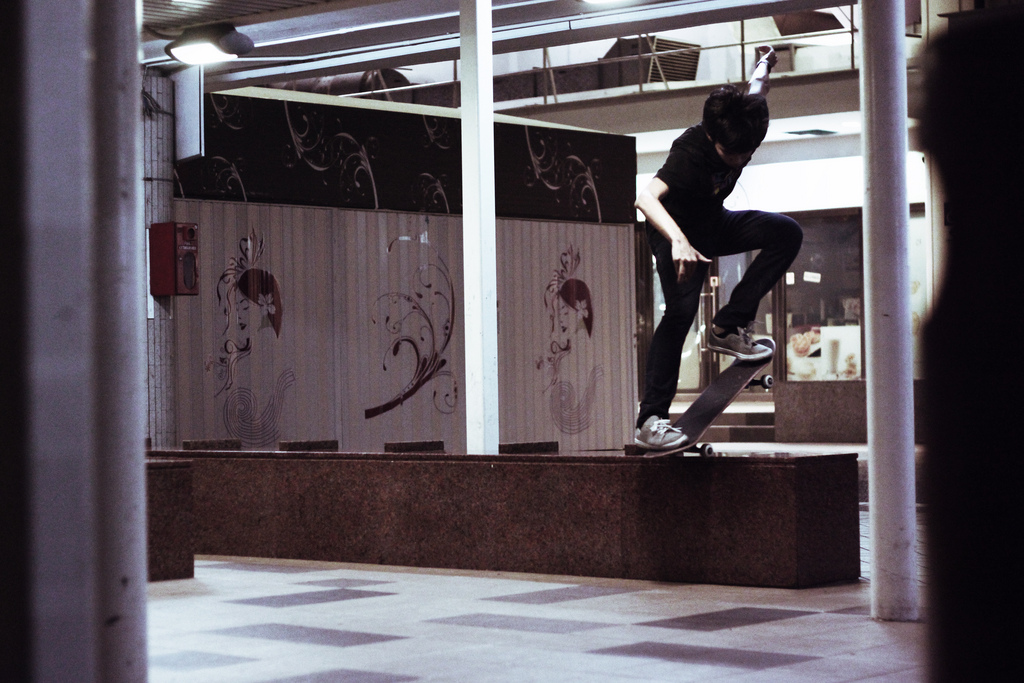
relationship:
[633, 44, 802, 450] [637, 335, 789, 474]
guy on a skateboard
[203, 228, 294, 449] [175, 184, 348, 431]
design on wall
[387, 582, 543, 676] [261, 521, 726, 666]
tile on floor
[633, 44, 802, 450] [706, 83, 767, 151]
guy with hair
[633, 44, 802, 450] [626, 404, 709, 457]
guy wearing shoe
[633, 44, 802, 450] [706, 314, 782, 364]
guy wearing shoe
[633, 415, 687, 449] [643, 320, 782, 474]
shoe on skateboard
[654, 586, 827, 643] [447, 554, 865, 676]
tile on floor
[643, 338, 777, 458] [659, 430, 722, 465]
skateboard with wheel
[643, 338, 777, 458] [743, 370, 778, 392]
skateboard with wheel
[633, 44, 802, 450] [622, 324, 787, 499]
guy on a skateboard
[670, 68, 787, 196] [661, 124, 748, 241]
guy wearing a shirt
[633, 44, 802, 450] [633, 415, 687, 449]
guy wearing shoe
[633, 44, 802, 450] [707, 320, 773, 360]
guy wearing shoe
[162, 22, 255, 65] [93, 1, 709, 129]
light on ceiling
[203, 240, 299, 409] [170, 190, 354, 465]
design on wall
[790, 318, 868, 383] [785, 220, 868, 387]
posters on window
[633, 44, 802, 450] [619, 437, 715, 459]
guy on skateboard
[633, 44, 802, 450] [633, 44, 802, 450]
guy doing guy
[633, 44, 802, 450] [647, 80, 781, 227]
guy wears shirt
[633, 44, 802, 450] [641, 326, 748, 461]
guy wears shoes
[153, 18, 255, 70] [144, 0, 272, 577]
light on side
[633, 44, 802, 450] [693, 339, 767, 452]
guy on skateboard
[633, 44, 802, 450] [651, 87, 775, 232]
guy wears shirt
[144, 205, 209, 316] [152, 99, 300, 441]
box on wall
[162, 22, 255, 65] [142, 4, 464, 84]
light on ceiling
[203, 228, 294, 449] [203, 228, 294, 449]
design has design